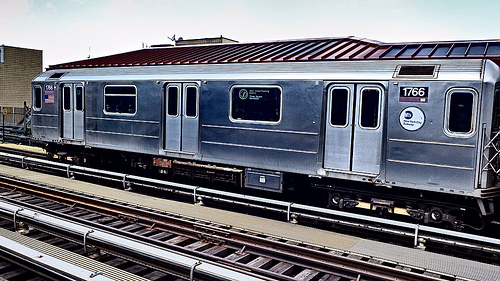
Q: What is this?
A: A train.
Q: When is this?
A: Daytime.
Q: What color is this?
A: Silver.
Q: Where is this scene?
A: On the train tracks.